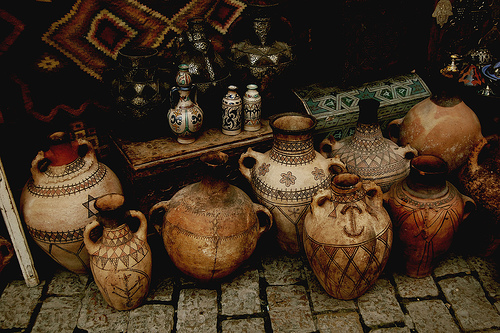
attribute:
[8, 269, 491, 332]
ground — brick, cement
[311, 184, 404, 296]
pot — dirty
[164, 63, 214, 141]
flask — white, small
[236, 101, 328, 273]
jug — shiny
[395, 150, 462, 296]
vase — big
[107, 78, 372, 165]
table — brown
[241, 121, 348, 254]
vase — white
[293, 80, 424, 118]
box — green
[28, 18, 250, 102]
fabric — hanging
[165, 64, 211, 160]
urn — white, light brown, beige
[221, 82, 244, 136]
ewer — ceramic, small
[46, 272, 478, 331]
floor — gray, brick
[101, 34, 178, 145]
pot — brown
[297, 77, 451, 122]
chest — turquoise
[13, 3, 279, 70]
pattern — checkered, large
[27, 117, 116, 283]
jug — red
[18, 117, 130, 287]
urn — large, beige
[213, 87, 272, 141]
jugs — white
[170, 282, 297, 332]
tiles — blue-green, gray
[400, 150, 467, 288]
urn — reddish brown